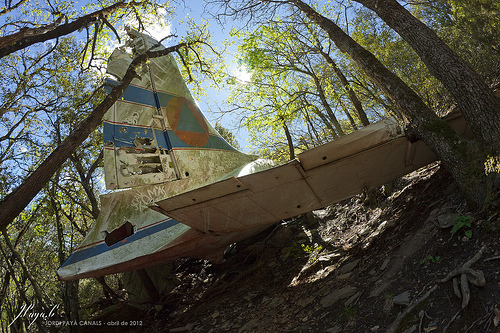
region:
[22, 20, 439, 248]
an empty deserted sail boat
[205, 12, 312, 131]
the sun clouds are through the trees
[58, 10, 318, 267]
the boat is dirty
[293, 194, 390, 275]
the sun is on the ground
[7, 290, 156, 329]
white writing on the bottom left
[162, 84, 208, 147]
an orange circle on the boat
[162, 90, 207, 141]
a triangle in the middle of the circle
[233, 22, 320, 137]
the leaves on the trees are green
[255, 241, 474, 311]
sticks and rocks on the ground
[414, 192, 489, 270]
greenery growing out of the dirt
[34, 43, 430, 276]
Small boat in the woods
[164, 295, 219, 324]
Small patch of brown dirt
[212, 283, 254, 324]
Small patch of brown dirt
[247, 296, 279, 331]
Small patch of brown dirt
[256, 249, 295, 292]
Small patch of brown dirt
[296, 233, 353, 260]
Small patch of brown dirt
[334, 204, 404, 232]
Small patch of brown dirt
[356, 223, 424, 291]
Small patch of brown dirt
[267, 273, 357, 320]
Small patch of brown dirt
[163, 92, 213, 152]
blue triangle on an airplane tail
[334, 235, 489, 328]
roots of a tree on the ground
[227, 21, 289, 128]
sunlight seen through the trees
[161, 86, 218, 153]
yellow circle with a blue triangle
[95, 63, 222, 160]
blue stripes on an airplane tail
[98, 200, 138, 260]
hole in the back of an airplane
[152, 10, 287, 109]
blue sky seen through the trees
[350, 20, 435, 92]
green leaves on the trees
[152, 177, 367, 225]
underside of an airplane wing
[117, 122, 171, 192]
holes on the back of an airplane tail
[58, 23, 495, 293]
remains of plane crshed into the forest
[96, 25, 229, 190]
rear blue and white tail of airplane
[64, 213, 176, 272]
blue and red stripe along torn plane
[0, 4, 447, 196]
bright blue sky with sun shining in clouds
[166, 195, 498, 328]
forest floor filled with dead wood and twigs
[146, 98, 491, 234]
side white metal flaps of remaining plane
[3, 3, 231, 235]
two tall tree trunks in foreground of picture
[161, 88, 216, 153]
orange circle with blue triangle symbol on wing of plane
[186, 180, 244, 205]
screw holes in flaps of plane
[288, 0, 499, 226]
two tall tree trunks wedged into train wreckage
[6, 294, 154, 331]
White letters in the corner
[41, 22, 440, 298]
There are stripes on the plane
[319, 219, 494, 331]
branches on the hill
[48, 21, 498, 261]
The plane has crashed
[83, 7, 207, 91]
Clouds in the sky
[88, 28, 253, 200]
White, red, orange colors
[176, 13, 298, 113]
It is sunny outside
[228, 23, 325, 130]
Light green leaves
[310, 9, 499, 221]
Trees are high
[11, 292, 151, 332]
Copyright in the corner